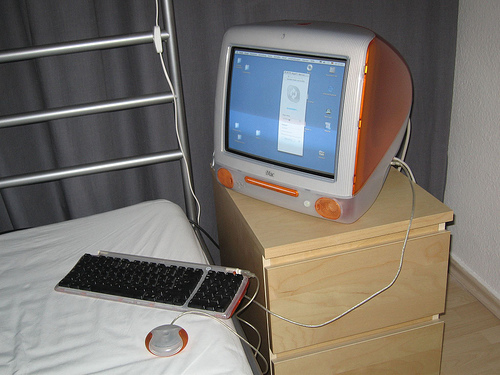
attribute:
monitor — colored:
[210, 19, 415, 225]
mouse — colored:
[144, 326, 189, 358]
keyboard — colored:
[54, 249, 252, 320]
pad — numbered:
[188, 270, 243, 312]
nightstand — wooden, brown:
[214, 166, 455, 375]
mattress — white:
[1, 198, 256, 375]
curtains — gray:
[1, 0, 459, 265]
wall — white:
[443, 2, 499, 318]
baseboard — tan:
[446, 254, 499, 321]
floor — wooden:
[440, 272, 500, 374]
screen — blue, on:
[226, 48, 346, 179]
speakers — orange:
[217, 167, 341, 221]